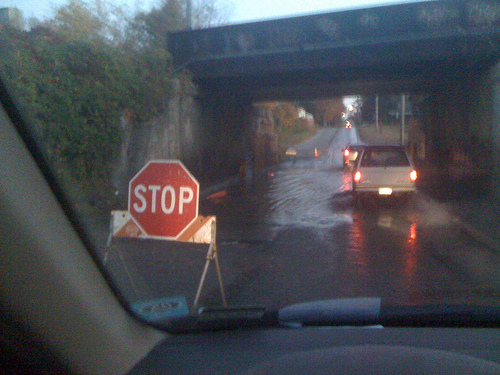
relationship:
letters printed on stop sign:
[133, 185, 194, 217] [125, 159, 201, 241]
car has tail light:
[350, 145, 418, 205] [410, 169, 418, 183]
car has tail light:
[350, 145, 418, 205] [352, 170, 360, 184]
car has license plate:
[350, 145, 418, 205] [376, 186, 393, 195]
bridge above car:
[166, 0, 499, 99] [350, 145, 418, 205]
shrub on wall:
[5, 24, 201, 216] [39, 75, 287, 209]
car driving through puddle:
[350, 145, 418, 205] [213, 168, 461, 226]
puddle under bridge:
[213, 168, 461, 226] [166, 0, 499, 99]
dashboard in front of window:
[112, 325, 499, 373] [0, 1, 499, 330]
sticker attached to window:
[129, 293, 189, 325] [0, 1, 499, 330]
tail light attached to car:
[344, 147, 352, 158] [343, 143, 369, 167]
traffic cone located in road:
[312, 147, 319, 152] [88, 124, 500, 308]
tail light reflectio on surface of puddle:
[408, 221, 418, 239] [213, 168, 461, 226]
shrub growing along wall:
[5, 24, 201, 216] [39, 75, 287, 209]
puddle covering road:
[213, 168, 461, 226] [88, 124, 500, 308]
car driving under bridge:
[350, 145, 418, 205] [166, 0, 499, 99]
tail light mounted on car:
[410, 169, 418, 183] [350, 145, 418, 205]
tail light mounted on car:
[352, 170, 360, 184] [350, 145, 418, 205]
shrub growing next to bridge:
[5, 24, 201, 216] [166, 0, 499, 99]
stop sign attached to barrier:
[125, 159, 201, 241] [104, 211, 229, 311]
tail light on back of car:
[410, 169, 418, 183] [350, 145, 418, 205]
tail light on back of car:
[352, 170, 360, 184] [350, 145, 418, 205]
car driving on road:
[350, 145, 418, 205] [88, 124, 500, 308]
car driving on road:
[343, 143, 369, 167] [88, 124, 500, 308]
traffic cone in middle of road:
[312, 147, 319, 152] [88, 124, 500, 308]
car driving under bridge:
[343, 143, 369, 167] [166, 0, 499, 99]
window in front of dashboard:
[0, 1, 499, 330] [112, 325, 499, 373]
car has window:
[350, 145, 418, 205] [361, 146, 409, 169]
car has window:
[343, 143, 369, 167] [348, 145, 363, 153]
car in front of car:
[343, 143, 369, 167] [350, 145, 418, 205]